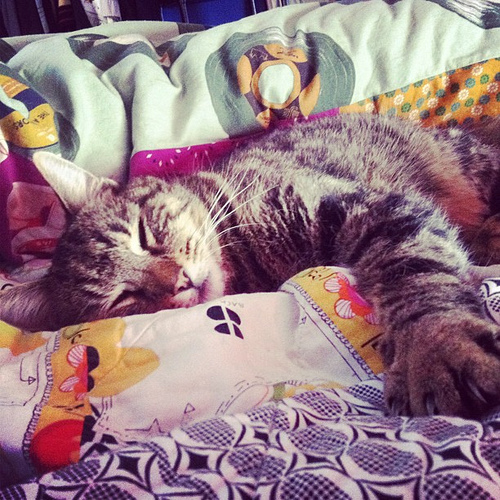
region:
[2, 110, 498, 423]
a cat sleeping on blankets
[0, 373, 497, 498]
blue and white patterned blanket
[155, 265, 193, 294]
nose of sleeping cat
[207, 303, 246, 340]
divided dark colored circle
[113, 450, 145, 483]
dark blue diamond shape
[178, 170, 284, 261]
long white facial whiskers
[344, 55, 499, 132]
yellow, white, and green pattern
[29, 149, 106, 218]
left ear of cat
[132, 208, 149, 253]
left eye of cat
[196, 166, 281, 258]
whiskers on the cat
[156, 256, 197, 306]
nose on the cat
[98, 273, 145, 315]
eye of the cat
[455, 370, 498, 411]
claw on the paw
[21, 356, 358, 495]
print on the comforter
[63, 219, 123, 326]
stripes on the cat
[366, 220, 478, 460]
arm of the cat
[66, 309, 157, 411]
seam on the comforter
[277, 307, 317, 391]
stitching on the seam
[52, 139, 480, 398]
cat sleeping on the bed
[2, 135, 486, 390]
cat with ears up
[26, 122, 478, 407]
cat with claws out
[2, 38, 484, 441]
vat laying on a blanket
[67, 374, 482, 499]
blue and white blanket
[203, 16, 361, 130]
gray cirle with yellow in the middle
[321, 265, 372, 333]
orange and pink fish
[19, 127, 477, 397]
cat's whiskers are white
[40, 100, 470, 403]
cat is brown and black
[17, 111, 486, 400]
Cat sleeping on a bed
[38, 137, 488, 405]
cat lying on bed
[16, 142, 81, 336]
cat has grey ears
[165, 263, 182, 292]
cat has grey nose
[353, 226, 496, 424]
cat has brown paws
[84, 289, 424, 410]
white blanket near cat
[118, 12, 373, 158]
grey and red pillow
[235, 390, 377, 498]
blue and white pillow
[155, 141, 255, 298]
cat has white whiskers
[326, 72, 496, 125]
yellow stripe on blanket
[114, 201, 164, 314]
cat has eyes closed